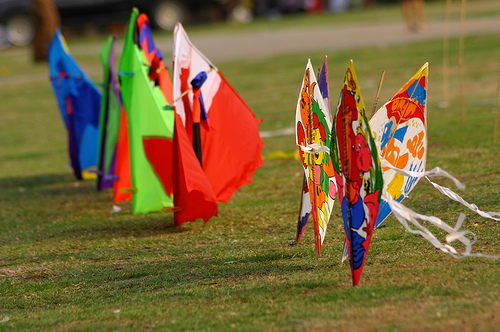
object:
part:
[0, 261, 163, 317]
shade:
[0, 246, 316, 290]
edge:
[172, 22, 183, 227]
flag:
[171, 19, 265, 228]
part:
[375, 253, 499, 332]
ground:
[0, 0, 498, 332]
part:
[0, 0, 45, 50]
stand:
[31, 0, 432, 64]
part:
[437, 166, 466, 191]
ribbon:
[378, 158, 500, 262]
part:
[34, 26, 60, 63]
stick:
[34, 1, 61, 62]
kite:
[330, 60, 385, 287]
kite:
[117, 6, 176, 215]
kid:
[301, 70, 329, 232]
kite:
[47, 28, 102, 180]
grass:
[1, 0, 500, 332]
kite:
[294, 58, 338, 257]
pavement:
[186, 17, 499, 67]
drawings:
[174, 46, 208, 170]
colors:
[331, 60, 382, 289]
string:
[379, 190, 472, 257]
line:
[47, 5, 429, 288]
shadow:
[0, 211, 185, 246]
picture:
[0, 0, 499, 331]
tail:
[262, 151, 299, 162]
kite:
[369, 61, 500, 260]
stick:
[349, 61, 357, 293]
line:
[260, 124, 295, 140]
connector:
[317, 56, 331, 113]